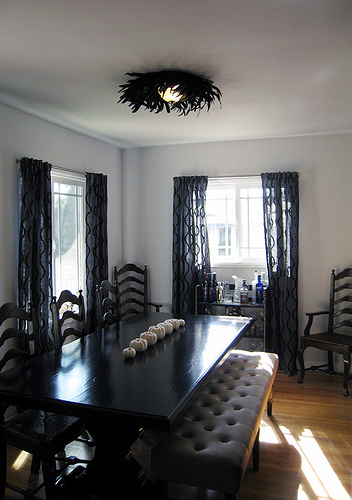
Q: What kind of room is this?
A: A dining room.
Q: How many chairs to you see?
A: 5.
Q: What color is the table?
A: Black.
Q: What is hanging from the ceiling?
A: A light.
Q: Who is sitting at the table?
A: No one.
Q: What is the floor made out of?
A: Wood.